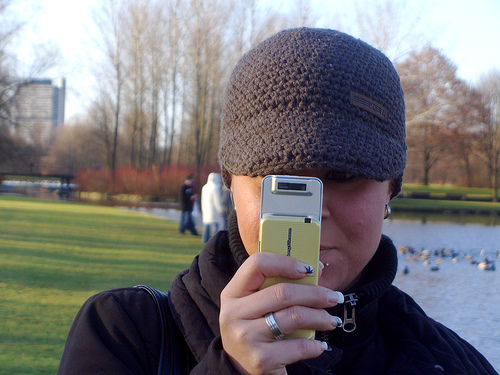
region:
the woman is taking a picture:
[242, 160, 344, 295]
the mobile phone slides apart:
[245, 164, 377, 304]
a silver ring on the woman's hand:
[227, 265, 303, 342]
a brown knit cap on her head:
[205, 22, 447, 207]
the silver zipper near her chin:
[319, 278, 368, 351]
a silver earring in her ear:
[360, 155, 405, 243]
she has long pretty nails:
[284, 253, 352, 370]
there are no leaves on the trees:
[91, 26, 241, 217]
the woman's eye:
[310, 160, 401, 245]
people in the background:
[166, 158, 264, 265]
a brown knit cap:
[217, 25, 407, 177]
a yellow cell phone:
[256, 172, 316, 284]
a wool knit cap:
[216, 25, 401, 185]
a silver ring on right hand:
[261, 310, 281, 335]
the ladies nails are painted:
[295, 260, 312, 272]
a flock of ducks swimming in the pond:
[397, 240, 497, 287]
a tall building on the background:
[3, 75, 68, 152]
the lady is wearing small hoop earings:
[383, 202, 391, 222]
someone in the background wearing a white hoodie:
[201, 171, 228, 229]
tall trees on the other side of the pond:
[77, 0, 183, 200]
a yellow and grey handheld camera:
[262, 177, 316, 342]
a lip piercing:
[322, 258, 332, 270]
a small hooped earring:
[385, 203, 392, 217]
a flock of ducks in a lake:
[394, 239, 499, 279]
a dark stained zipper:
[342, 292, 356, 333]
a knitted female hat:
[219, 28, 404, 199]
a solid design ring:
[262, 315, 283, 336]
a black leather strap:
[128, 284, 185, 374]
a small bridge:
[0, 170, 79, 192]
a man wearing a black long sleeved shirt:
[179, 174, 197, 235]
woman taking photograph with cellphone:
[60, 21, 495, 368]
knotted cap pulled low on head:
[215, 25, 400, 205]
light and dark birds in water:
[395, 220, 495, 281]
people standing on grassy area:
[1, 175, 228, 246]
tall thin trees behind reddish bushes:
[90, 5, 210, 200]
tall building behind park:
[2, 71, 63, 166]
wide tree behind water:
[395, 36, 490, 191]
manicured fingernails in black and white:
[292, 255, 343, 357]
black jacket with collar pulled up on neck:
[60, 210, 490, 370]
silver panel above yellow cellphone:
[258, 171, 321, 261]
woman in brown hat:
[58, 27, 498, 374]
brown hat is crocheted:
[217, 27, 407, 199]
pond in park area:
[109, 202, 499, 373]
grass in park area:
[1, 193, 201, 374]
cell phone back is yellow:
[257, 213, 318, 338]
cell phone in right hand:
[217, 173, 344, 373]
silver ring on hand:
[262, 312, 284, 339]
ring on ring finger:
[262, 312, 283, 340]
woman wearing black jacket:
[55, 207, 498, 373]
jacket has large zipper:
[340, 292, 357, 332]